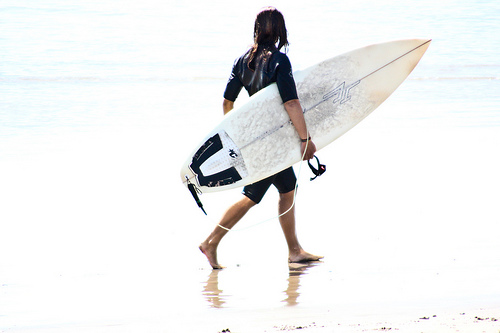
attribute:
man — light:
[192, 4, 332, 271]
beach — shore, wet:
[13, 142, 497, 332]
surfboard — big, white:
[177, 35, 436, 201]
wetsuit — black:
[220, 47, 300, 204]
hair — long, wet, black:
[242, 6, 292, 68]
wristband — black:
[297, 133, 315, 146]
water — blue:
[1, 1, 499, 128]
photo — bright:
[1, 1, 499, 332]